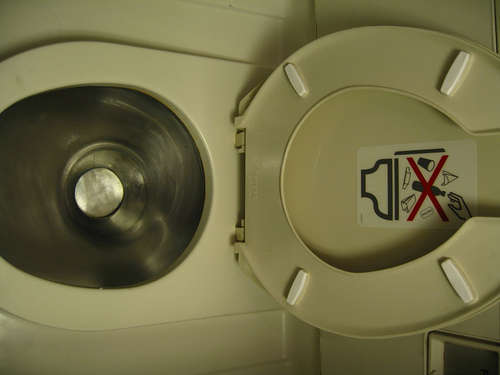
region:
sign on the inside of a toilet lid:
[347, 131, 469, 228]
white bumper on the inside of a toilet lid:
[279, 63, 310, 102]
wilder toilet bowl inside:
[44, 131, 137, 232]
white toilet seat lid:
[26, 21, 218, 351]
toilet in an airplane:
[32, 21, 479, 363]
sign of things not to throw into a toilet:
[360, 140, 482, 235]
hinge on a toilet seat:
[222, 97, 256, 284]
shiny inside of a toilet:
[22, 131, 144, 245]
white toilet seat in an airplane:
[22, 38, 285, 345]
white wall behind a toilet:
[317, 336, 369, 360]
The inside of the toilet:
[31, 130, 157, 259]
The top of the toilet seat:
[260, 33, 495, 333]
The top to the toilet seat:
[316, 113, 428, 231]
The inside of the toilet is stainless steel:
[31, 119, 174, 256]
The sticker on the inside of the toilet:
[359, 130, 466, 230]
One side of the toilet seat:
[245, 187, 499, 338]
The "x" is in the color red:
[400, 147, 467, 235]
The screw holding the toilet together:
[228, 215, 248, 255]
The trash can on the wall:
[424, 332, 499, 373]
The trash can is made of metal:
[426, 338, 498, 373]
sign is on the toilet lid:
[343, 138, 477, 228]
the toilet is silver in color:
[53, 136, 183, 253]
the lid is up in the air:
[225, 43, 498, 331]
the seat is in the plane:
[4, 8, 496, 354]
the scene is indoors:
[11, 18, 498, 373]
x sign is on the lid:
[372, 140, 457, 230]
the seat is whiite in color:
[8, 6, 486, 373]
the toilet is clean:
[4, 67, 211, 298]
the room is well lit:
[2, 6, 497, 373]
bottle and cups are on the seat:
[381, 148, 483, 240]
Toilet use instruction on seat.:
[360, 143, 472, 225]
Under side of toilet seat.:
[245, 38, 498, 333]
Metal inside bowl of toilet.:
[22, 116, 177, 256]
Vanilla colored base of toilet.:
[1, 37, 240, 338]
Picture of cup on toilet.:
[416, 153, 434, 173]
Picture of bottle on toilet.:
[412, 183, 446, 196]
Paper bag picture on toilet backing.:
[402, 196, 418, 214]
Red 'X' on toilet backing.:
[406, 152, 448, 224]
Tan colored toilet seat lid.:
[247, 23, 497, 342]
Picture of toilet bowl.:
[361, 158, 394, 225]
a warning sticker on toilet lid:
[356, 102, 468, 273]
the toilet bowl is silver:
[29, 98, 188, 263]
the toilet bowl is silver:
[44, 160, 145, 272]